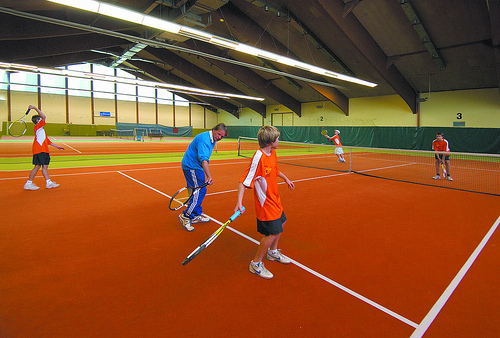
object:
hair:
[256, 125, 279, 148]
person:
[429, 131, 453, 181]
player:
[321, 129, 348, 164]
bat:
[178, 205, 249, 266]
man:
[177, 122, 230, 234]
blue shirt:
[180, 128, 217, 172]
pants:
[179, 163, 206, 219]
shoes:
[244, 259, 274, 282]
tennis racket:
[163, 175, 213, 211]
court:
[0, 133, 500, 337]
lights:
[210, 35, 238, 50]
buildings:
[0, 0, 500, 336]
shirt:
[238, 147, 298, 224]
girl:
[22, 103, 68, 190]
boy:
[234, 123, 298, 279]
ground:
[0, 136, 500, 337]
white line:
[114, 170, 422, 329]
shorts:
[33, 151, 55, 168]